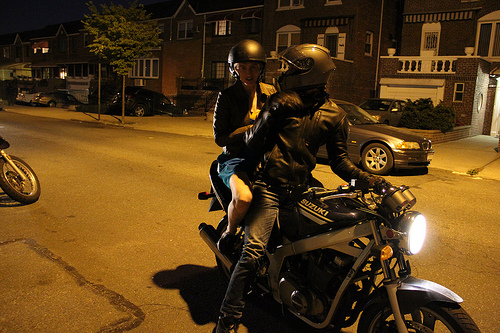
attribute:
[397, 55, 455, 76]
balcony — white, wooden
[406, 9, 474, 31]
stripee — white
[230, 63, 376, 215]
jacket — leather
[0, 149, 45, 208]
tire — rubber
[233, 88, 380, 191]
jacket — black, leather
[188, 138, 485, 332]
motorcycle — suzuki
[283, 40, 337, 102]
helmet — grey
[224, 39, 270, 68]
helmet — black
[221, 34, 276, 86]
helmet — black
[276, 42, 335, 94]
helmet — black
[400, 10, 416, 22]
stripe — white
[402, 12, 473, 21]
stripe — white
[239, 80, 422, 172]
bmw — blue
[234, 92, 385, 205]
jacket — black, leather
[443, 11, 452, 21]
stripe — white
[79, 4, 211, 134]
tree — small, green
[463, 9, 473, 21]
stripe — white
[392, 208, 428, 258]
headlight — brightly lit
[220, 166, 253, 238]
leg — bare